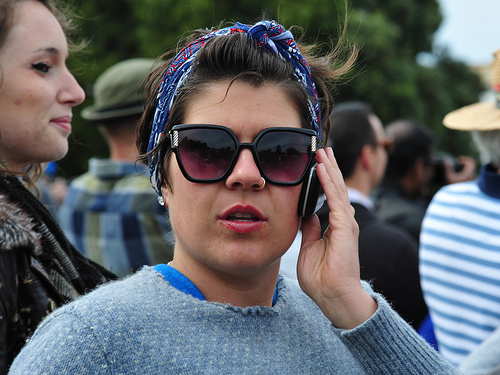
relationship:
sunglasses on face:
[150, 123, 317, 187] [164, 68, 302, 275]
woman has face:
[6, 20, 454, 374] [164, 68, 302, 275]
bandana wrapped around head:
[144, 21, 329, 196] [140, 22, 326, 286]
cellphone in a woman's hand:
[293, 144, 348, 230] [309, 144, 346, 329]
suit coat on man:
[312, 203, 430, 324] [5, 24, 462, 372]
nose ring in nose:
[256, 177, 266, 190] [227, 150, 267, 192]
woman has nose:
[6, 20, 454, 374] [227, 150, 267, 192]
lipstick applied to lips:
[234, 220, 264, 226] [214, 203, 269, 235]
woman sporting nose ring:
[6, 20, 454, 374] [255, 180, 269, 189]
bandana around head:
[144, 21, 329, 196] [140, 22, 326, 286]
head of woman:
[140, 22, 326, 286] [6, 20, 454, 374]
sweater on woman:
[8, 265, 479, 375] [6, 20, 454, 374]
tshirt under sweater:
[156, 252, 216, 301] [74, 262, 419, 372]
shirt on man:
[414, 162, 492, 367] [414, 52, 499, 371]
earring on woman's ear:
[156, 195, 166, 207] [151, 166, 172, 206]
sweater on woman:
[8, 265, 460, 374] [6, 20, 454, 374]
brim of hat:
[443, 103, 498, 133] [444, 60, 499, 135]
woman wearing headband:
[6, 20, 454, 374] [144, 21, 319, 196]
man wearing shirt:
[414, 52, 499, 371] [420, 165, 499, 367]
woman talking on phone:
[6, 20, 454, 374] [294, 154, 321, 228]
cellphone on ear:
[295, 164, 325, 218] [311, 148, 330, 196]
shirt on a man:
[58, 158, 175, 278] [55, 56, 172, 280]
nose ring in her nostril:
[226, 147, 265, 190] [250, 171, 264, 190]